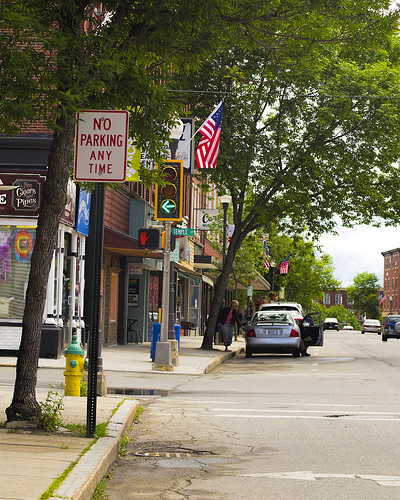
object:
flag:
[194, 102, 224, 170]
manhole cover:
[134, 440, 198, 460]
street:
[94, 319, 400, 498]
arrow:
[241, 461, 399, 489]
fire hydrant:
[61, 333, 88, 399]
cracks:
[121, 398, 227, 498]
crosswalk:
[138, 389, 399, 423]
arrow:
[162, 200, 176, 213]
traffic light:
[154, 159, 183, 222]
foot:
[301, 352, 311, 357]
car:
[245, 308, 324, 358]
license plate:
[266, 328, 279, 336]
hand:
[139, 230, 149, 246]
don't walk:
[139, 229, 150, 245]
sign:
[74, 108, 130, 184]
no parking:
[80, 117, 124, 148]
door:
[299, 311, 324, 349]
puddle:
[106, 382, 169, 396]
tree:
[189, 0, 399, 352]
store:
[0, 135, 105, 363]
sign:
[10, 176, 41, 213]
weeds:
[37, 383, 55, 432]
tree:
[0, 0, 307, 417]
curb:
[47, 396, 143, 499]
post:
[150, 154, 184, 374]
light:
[160, 114, 185, 143]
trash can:
[150, 322, 182, 364]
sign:
[76, 188, 92, 238]